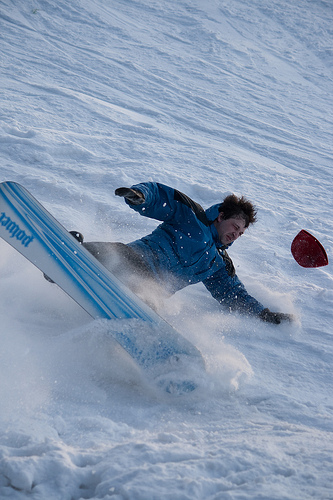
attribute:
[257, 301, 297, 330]
glove — black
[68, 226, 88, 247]
shoe — black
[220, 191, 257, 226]
hair — brown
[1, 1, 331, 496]
snow — packed, white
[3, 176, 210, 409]
snowboard — white, blue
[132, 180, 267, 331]
parka — blue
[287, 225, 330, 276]
hat — knit, red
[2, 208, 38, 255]
logo — blue